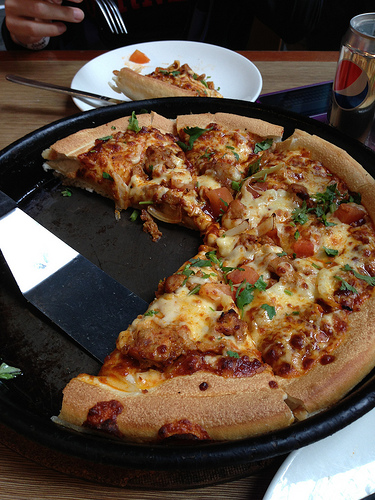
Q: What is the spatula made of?
A: Metal.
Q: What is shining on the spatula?
A: Light.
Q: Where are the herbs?
A: On the pizza.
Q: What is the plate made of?
A: Porcelain.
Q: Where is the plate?
A: On the table.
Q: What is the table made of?
A: Wood.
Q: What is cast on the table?
A: Shadows.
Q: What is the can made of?
A: Aluminum.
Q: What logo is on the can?
A: Pepsi.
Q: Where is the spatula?
A: Resting in the pizza tray.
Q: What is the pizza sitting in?
A: A black dish.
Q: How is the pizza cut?
A: It is sliced into wedges.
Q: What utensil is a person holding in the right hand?
A: Fork.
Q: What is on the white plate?
A: One slice of pizza.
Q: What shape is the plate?
A: Round.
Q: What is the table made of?
A: Wood.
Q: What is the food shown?
A: Pizza.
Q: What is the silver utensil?
A: A spatula.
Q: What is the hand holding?
A: A fork.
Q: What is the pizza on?
A: A pizza pan.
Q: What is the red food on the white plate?
A: A tomato.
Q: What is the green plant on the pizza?
A: Basil.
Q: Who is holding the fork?
A: A man or woman.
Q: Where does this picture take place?
A: At a table.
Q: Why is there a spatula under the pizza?
A: It is there to lift the pizza.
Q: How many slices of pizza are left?
A: Six.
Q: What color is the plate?
A: White.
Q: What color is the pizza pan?
A: Black.